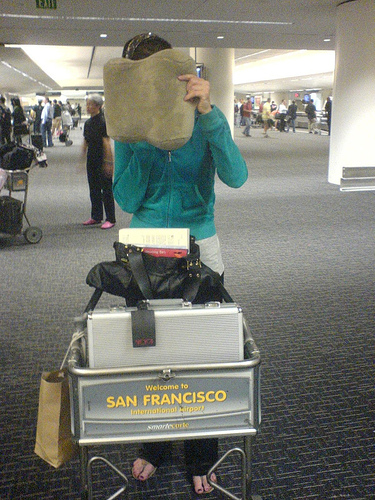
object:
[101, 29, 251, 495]
woman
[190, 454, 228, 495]
sandals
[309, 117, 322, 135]
baggage return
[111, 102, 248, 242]
fabric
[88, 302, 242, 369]
carry case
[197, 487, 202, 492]
toenail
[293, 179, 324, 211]
floor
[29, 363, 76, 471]
brown bag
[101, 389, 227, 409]
san francisco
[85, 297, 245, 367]
briefcase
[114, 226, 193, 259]
book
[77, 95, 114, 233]
person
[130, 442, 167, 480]
foot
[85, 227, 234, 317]
bag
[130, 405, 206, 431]
text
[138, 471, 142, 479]
toes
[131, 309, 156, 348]
tag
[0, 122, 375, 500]
carpet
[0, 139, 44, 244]
cart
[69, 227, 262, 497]
cart